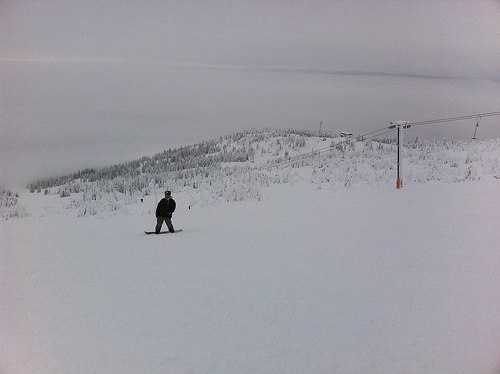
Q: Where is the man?
A: Standing in the snow.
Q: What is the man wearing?
A: A coat.